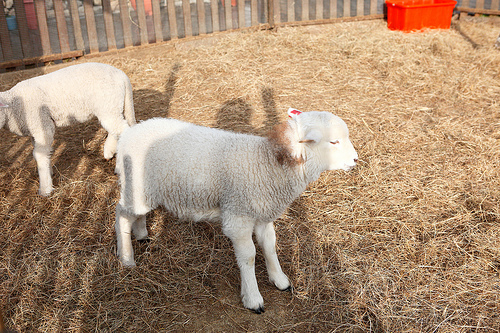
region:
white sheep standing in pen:
[101, 105, 347, 312]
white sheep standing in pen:
[8, 63, 128, 179]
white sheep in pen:
[7, 58, 141, 182]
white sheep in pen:
[120, 102, 342, 305]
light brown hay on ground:
[172, 46, 247, 73]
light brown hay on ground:
[17, 212, 77, 244]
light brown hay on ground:
[307, 226, 410, 311]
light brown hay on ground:
[388, 128, 476, 216]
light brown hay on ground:
[285, 35, 425, 97]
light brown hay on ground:
[11, 202, 106, 308]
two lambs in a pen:
[28, 24, 394, 329]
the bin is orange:
[378, 8, 473, 65]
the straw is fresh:
[315, 38, 476, 203]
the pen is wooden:
[31, 21, 271, 144]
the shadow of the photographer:
[46, 20, 351, 262]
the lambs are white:
[27, 49, 420, 288]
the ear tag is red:
[287, 99, 312, 129]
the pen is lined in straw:
[18, 34, 378, 272]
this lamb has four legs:
[66, 61, 424, 302]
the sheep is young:
[114, 79, 379, 262]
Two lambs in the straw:
[0, 60, 357, 315]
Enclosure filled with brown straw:
[0, 0, 495, 325]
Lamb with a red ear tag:
[110, 105, 355, 305]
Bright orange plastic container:
[380, 0, 455, 30]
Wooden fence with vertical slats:
[0, 0, 495, 70]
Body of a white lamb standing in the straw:
[0, 60, 135, 195]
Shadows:
[10, 60, 355, 325]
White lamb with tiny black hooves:
[110, 105, 355, 315]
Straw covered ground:
[0, 10, 495, 325]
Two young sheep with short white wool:
[0, 57, 361, 312]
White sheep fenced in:
[112, 110, 412, 322]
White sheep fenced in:
[2, 55, 150, 201]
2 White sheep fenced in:
[5, 34, 358, 321]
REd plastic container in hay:
[384, 0, 464, 32]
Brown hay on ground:
[408, 225, 498, 315]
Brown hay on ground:
[420, 106, 492, 186]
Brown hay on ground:
[400, 54, 499, 82]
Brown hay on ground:
[231, 33, 339, 73]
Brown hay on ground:
[30, 248, 100, 310]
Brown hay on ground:
[123, 54, 220, 99]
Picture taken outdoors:
[50, 45, 456, 296]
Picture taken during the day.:
[28, 33, 498, 328]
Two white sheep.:
[26, 64, 388, 261]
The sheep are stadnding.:
[25, 57, 426, 282]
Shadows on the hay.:
[157, 68, 332, 147]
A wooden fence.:
[51, 19, 151, 39]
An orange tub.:
[378, 11, 454, 19]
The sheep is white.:
[154, 139, 249, 194]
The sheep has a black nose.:
[356, 154, 360, 165]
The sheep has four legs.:
[109, 203, 338, 327]